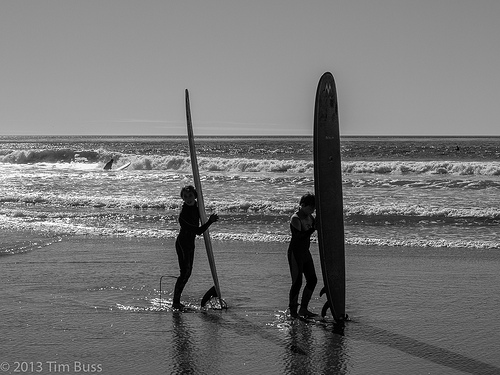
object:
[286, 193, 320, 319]
lady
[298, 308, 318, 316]
girl's feet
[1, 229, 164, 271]
water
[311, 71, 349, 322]
surfboard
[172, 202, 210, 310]
wetsuit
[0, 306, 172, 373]
beach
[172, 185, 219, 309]
girl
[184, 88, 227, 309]
surfboard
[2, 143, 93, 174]
waves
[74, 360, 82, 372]
letters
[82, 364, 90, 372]
letter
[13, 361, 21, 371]
numbers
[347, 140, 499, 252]
waves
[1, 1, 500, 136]
sky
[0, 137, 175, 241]
ocean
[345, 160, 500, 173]
surf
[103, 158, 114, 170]
surfer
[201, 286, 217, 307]
fin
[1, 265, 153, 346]
water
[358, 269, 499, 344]
shore